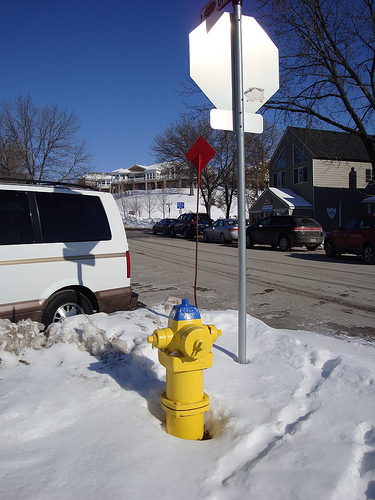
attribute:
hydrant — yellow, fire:
[146, 299, 222, 441]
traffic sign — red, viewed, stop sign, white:
[189, 3, 282, 131]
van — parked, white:
[1, 179, 138, 323]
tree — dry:
[245, 5, 373, 169]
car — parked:
[249, 214, 321, 250]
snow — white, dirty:
[3, 300, 373, 499]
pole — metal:
[231, 6, 248, 362]